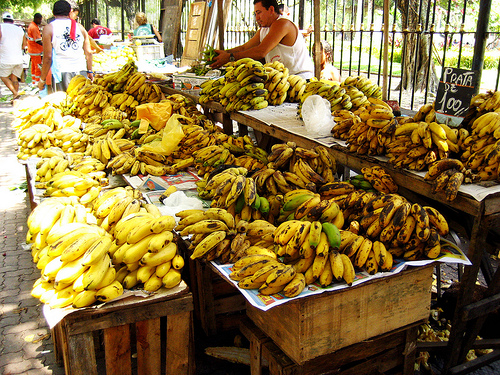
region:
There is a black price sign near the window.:
[431, 58, 476, 120]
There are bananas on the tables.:
[299, 75, 499, 199]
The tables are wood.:
[296, 263, 435, 363]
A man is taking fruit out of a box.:
[203, 1, 322, 82]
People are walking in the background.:
[24, 3, 94, 89]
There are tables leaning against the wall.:
[182, 0, 219, 57]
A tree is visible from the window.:
[384, 1, 442, 98]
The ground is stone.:
[1, 276, 60, 372]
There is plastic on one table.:
[297, 93, 341, 139]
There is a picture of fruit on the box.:
[171, 61, 217, 103]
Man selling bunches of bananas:
[211, 0, 318, 80]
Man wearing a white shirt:
[210, 0, 315, 80]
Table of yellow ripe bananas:
[5, 85, 190, 317]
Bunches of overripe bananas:
[200, 49, 498, 214]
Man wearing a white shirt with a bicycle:
[32, 0, 95, 95]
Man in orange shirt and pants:
[23, 11, 45, 84]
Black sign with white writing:
[430, 63, 475, 130]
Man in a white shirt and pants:
[0, 13, 24, 99]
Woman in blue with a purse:
[128, 9, 161, 41]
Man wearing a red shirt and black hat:
[84, 13, 113, 39]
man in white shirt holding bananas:
[199, 0, 314, 74]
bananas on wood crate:
[264, 213, 441, 363]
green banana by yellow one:
[306, 221, 342, 248]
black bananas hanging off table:
[426, 156, 464, 205]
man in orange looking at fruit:
[25, 9, 45, 86]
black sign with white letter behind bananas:
[435, 65, 479, 123]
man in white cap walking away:
[0, 11, 27, 92]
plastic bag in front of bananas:
[302, 93, 334, 142]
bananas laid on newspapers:
[245, 96, 297, 116]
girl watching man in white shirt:
[312, 42, 341, 79]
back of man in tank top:
[41, 1, 91, 86]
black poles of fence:
[209, 3, 492, 109]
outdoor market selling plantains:
[24, 4, 499, 371]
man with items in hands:
[204, 2, 311, 82]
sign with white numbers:
[433, 66, 473, 125]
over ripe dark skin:
[351, 194, 451, 261]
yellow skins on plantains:
[114, 212, 181, 292]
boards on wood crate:
[68, 299, 193, 373]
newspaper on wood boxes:
[146, 181, 464, 311]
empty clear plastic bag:
[300, 95, 337, 138]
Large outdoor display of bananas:
[27, 55, 497, 302]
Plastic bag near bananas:
[294, 91, 336, 136]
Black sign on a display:
[433, 64, 474, 126]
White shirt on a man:
[259, 15, 311, 76]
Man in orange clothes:
[28, 14, 43, 81]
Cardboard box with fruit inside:
[170, 69, 218, 89]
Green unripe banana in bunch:
[320, 212, 342, 254]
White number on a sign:
[438, 89, 460, 114]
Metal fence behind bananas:
[229, 4, 499, 100]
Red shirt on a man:
[89, 27, 112, 39]